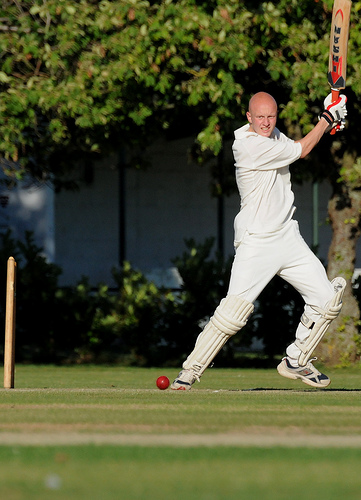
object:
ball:
[156, 376, 170, 390]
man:
[170, 91, 347, 391]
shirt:
[232, 122, 302, 245]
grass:
[0, 363, 360, 499]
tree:
[0, 1, 360, 163]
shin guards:
[182, 294, 254, 376]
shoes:
[276, 357, 330, 388]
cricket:
[325, 0, 353, 140]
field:
[0, 1, 360, 499]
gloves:
[323, 92, 347, 135]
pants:
[182, 219, 340, 387]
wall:
[0, 132, 359, 357]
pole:
[4, 254, 15, 388]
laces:
[178, 364, 201, 384]